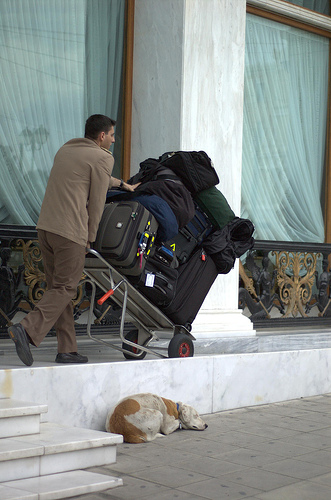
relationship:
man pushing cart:
[16, 111, 125, 365] [91, 238, 195, 358]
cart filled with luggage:
[91, 238, 195, 358] [97, 148, 254, 326]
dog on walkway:
[104, 389, 207, 443] [107, 393, 330, 498]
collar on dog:
[174, 400, 187, 431] [104, 389, 207, 443]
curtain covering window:
[3, 1, 330, 244] [2, 3, 330, 312]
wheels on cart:
[123, 326, 191, 362] [91, 238, 195, 358]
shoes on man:
[9, 320, 88, 373] [16, 111, 125, 365]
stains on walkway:
[126, 406, 311, 498] [107, 393, 330, 498]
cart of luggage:
[91, 238, 195, 358] [97, 148, 254, 326]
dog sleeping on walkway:
[104, 389, 207, 443] [107, 393, 330, 498]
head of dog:
[182, 404, 211, 438] [104, 389, 207, 443]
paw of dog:
[170, 422, 188, 434] [104, 389, 207, 443]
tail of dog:
[140, 432, 169, 446] [104, 389, 207, 443]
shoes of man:
[9, 320, 88, 373] [16, 111, 125, 365]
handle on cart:
[92, 287, 114, 306] [91, 238, 195, 358]